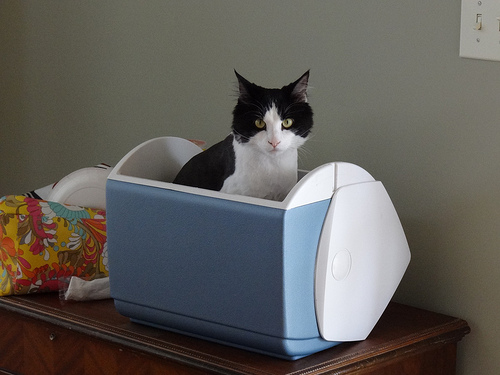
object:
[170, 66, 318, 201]
cat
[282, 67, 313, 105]
ear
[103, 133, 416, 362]
cooler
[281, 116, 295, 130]
eye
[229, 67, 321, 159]
head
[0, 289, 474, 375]
table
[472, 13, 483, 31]
light switch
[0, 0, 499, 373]
wall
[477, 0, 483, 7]
screw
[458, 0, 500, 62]
light plate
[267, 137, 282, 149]
nose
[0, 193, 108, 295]
bag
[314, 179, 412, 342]
cover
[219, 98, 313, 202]
hair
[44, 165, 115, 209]
items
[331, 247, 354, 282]
circle